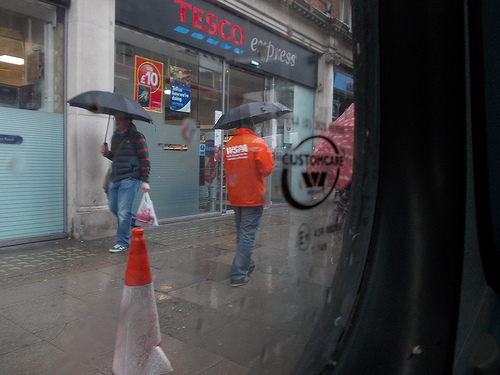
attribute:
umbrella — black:
[66, 90, 155, 125]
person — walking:
[218, 121, 273, 287]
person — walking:
[98, 112, 150, 254]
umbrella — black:
[213, 101, 293, 130]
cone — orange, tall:
[109, 226, 169, 375]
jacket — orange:
[221, 129, 273, 208]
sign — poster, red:
[134, 56, 164, 114]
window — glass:
[116, 23, 223, 222]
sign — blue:
[169, 65, 191, 113]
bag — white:
[134, 189, 159, 230]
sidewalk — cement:
[1, 204, 338, 375]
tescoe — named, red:
[174, 0, 246, 47]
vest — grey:
[110, 125, 141, 183]